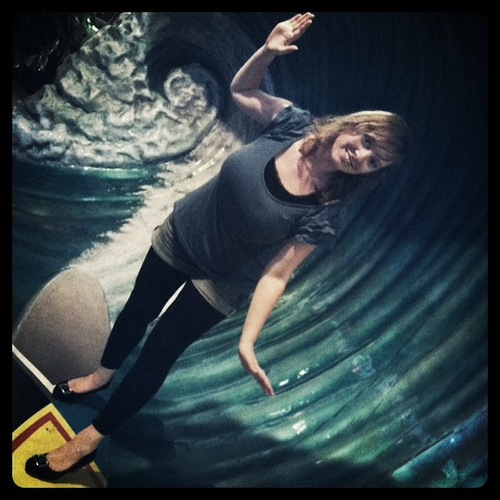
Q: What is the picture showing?
A: It is showing a tunnel.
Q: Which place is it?
A: It is a tunnel.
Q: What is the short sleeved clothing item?
A: The clothing item is a shirt.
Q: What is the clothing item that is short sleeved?
A: The clothing item is a shirt.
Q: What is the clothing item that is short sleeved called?
A: The clothing item is a shirt.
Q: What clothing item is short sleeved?
A: The clothing item is a shirt.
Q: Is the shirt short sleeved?
A: Yes, the shirt is short sleeved.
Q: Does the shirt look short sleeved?
A: Yes, the shirt is short sleeved.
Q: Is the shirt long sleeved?
A: No, the shirt is short sleeved.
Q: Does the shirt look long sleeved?
A: No, the shirt is short sleeved.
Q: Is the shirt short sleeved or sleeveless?
A: The shirt is short sleeved.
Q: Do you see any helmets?
A: No, there are no helmets.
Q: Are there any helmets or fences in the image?
A: No, there are no helmets or fences.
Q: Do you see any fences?
A: No, there are no fences.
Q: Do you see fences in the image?
A: No, there are no fences.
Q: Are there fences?
A: No, there are no fences.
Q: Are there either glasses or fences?
A: No, there are no fences or glasses.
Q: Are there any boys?
A: No, there are no boys.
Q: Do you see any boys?
A: No, there are no boys.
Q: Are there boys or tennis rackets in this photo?
A: No, there are no boys or tennis rackets.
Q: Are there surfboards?
A: Yes, there is a surfboard.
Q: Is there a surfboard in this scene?
A: Yes, there is a surfboard.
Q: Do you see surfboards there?
A: Yes, there is a surfboard.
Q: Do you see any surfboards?
A: Yes, there is a surfboard.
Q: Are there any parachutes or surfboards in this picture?
A: Yes, there is a surfboard.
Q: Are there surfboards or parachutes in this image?
A: Yes, there is a surfboard.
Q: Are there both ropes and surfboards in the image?
A: No, there is a surfboard but no ropes.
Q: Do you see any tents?
A: No, there are no tents.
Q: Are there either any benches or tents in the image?
A: No, there are no tents or benches.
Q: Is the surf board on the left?
A: Yes, the surf board is on the left of the image.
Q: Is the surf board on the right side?
A: No, the surf board is on the left of the image.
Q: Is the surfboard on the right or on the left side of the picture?
A: The surfboard is on the left of the image.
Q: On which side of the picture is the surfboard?
A: The surfboard is on the left of the image.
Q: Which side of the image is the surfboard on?
A: The surfboard is on the left of the image.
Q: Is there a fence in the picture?
A: No, there are no fences.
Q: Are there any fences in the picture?
A: No, there are no fences.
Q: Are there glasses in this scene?
A: No, there are no glasses.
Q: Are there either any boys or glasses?
A: No, there are no glasses or boys.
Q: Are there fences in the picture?
A: No, there are no fences.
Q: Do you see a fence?
A: No, there are no fences.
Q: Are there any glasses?
A: No, there are no glasses.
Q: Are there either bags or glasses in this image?
A: No, there are no glasses or bags.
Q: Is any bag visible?
A: No, there are no bags.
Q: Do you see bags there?
A: No, there are no bags.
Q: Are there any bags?
A: No, there are no bags.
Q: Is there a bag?
A: No, there are no bags.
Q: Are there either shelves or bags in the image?
A: No, there are no bags or shelves.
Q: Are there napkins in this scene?
A: No, there are no napkins.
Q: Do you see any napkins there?
A: No, there are no napkins.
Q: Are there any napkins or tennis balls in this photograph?
A: No, there are no napkins or tennis balls.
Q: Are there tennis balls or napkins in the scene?
A: No, there are no napkins or tennis balls.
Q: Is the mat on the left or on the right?
A: The mat is on the left of the image.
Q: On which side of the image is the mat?
A: The mat is on the left of the image.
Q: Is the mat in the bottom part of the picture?
A: Yes, the mat is in the bottom of the image.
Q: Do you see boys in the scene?
A: No, there are no boys.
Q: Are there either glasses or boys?
A: No, there are no boys or glasses.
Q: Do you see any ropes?
A: No, there are no ropes.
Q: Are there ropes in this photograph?
A: No, there are no ropes.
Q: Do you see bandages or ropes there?
A: No, there are no ropes or bandages.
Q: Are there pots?
A: No, there are no pots.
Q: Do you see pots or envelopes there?
A: No, there are no pots or envelopes.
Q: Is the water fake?
A: Yes, the water is fake.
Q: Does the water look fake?
A: Yes, the water is fake.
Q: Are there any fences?
A: No, there are no fences.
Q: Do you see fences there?
A: No, there are no fences.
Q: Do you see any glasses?
A: No, there are no glasses.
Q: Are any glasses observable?
A: No, there are no glasses.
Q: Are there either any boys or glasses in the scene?
A: No, there are no glasses or boys.